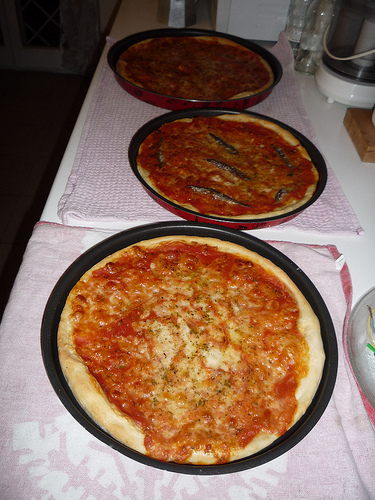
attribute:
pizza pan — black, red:
[126, 105, 329, 226]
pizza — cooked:
[141, 115, 316, 218]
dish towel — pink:
[55, 35, 364, 234]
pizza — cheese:
[78, 262, 333, 434]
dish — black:
[53, 218, 346, 492]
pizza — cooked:
[139, 95, 351, 231]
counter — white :
[3, 0, 374, 318]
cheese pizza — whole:
[54, 237, 329, 466]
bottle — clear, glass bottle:
[291, 2, 333, 78]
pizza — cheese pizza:
[117, 32, 276, 101]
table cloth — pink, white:
[95, 16, 364, 250]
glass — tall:
[277, 0, 312, 54]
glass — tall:
[291, 0, 336, 75]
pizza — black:
[53, 218, 350, 467]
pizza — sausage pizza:
[132, 93, 319, 225]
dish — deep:
[78, 18, 302, 118]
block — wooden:
[335, 94, 371, 184]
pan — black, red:
[87, 21, 343, 235]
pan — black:
[26, 217, 345, 487]